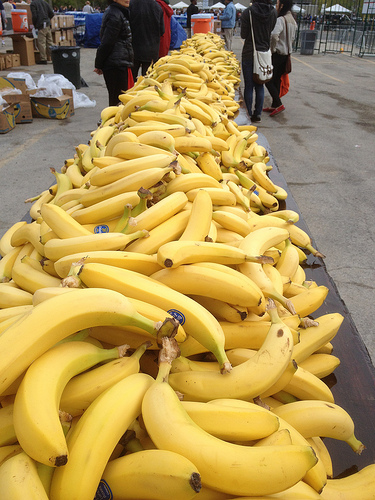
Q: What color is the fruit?
A: Yellow.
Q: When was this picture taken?
A: Daytime.